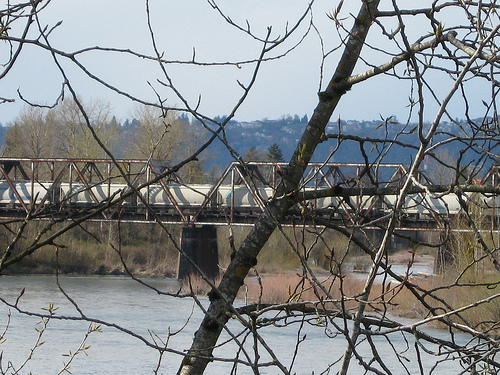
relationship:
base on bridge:
[174, 225, 219, 280] [2, 184, 489, 284]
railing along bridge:
[29, 149, 150, 216] [34, 143, 446, 233]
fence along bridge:
[0, 156, 498, 234] [0, 149, 496, 288]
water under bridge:
[0, 268, 497, 370] [0, 149, 496, 288]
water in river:
[0, 268, 497, 370] [1, 277, 498, 374]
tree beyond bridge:
[126, 95, 182, 190] [0, 149, 496, 288]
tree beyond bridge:
[175, 139, 204, 182] [0, 149, 496, 288]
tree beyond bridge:
[61, 92, 119, 182] [0, 149, 496, 288]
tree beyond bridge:
[3, 102, 62, 190] [0, 149, 496, 288]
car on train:
[0, 171, 56, 203] [4, 183, 499, 219]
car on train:
[59, 182, 131, 209] [4, 183, 499, 219]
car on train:
[134, 182, 214, 209] [4, 183, 499, 219]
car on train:
[213, 186, 304, 207] [4, 183, 499, 219]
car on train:
[384, 188, 475, 213] [4, 183, 499, 219]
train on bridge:
[4, 183, 499, 219] [4, 159, 498, 298]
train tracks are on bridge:
[8, 199, 498, 228] [11, 161, 271, 216]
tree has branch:
[3, 102, 62, 190] [68, 86, 133, 183]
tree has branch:
[126, 95, 182, 190] [80, 37, 154, 69]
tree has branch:
[3, 102, 62, 190] [88, 313, 155, 353]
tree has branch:
[3, 102, 62, 190] [268, 22, 320, 62]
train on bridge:
[0, 179, 499, 219] [3, 140, 491, 245]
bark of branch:
[232, 179, 427, 323] [154, 107, 381, 372]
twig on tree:
[86, 30, 191, 95] [196, 90, 386, 265]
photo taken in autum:
[44, 137, 398, 242] [142, 263, 292, 323]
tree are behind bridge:
[61, 92, 119, 182] [124, 145, 413, 249]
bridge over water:
[2, 184, 489, 284] [13, 274, 165, 336]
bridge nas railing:
[2, 184, 489, 284] [92, 157, 150, 222]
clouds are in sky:
[123, 24, 387, 118] [0, 0, 500, 136]